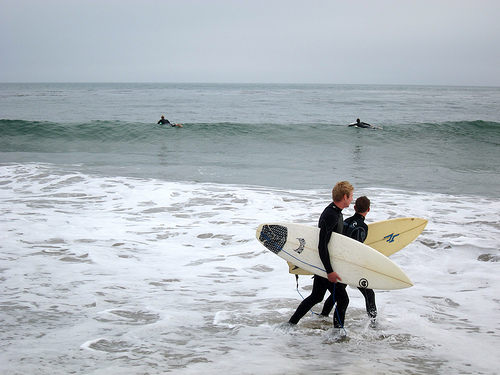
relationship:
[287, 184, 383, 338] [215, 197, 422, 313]
surfer carrying surfboard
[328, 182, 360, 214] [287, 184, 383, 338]
hair on head of surfer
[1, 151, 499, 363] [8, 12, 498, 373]
foam on bed beach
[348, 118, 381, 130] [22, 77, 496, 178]
people floating on top of wave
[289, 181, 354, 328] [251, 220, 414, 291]
man packing surfboard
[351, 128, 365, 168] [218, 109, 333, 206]
reflection on water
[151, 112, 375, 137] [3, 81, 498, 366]
people in ocean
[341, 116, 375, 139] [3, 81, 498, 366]
people in ocean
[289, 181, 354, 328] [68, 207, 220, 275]
man walking in ocean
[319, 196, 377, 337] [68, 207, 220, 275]
man walking in ocean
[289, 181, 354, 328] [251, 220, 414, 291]
man carrying surfboard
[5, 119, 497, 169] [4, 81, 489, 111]
wave in ocean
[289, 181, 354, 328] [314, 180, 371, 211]
man with hair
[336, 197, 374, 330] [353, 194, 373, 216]
man with hair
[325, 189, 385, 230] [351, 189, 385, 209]
man with hair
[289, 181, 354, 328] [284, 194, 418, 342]
man wearing wet suit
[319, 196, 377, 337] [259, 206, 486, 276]
man with surfboards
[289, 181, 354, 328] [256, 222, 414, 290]
man carrying surfboard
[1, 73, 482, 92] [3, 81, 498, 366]
horizon meets ocean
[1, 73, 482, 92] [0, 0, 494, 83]
horizon meets sky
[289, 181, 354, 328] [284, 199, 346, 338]
man wearing wet suit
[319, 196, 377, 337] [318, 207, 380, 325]
man wearing wet suit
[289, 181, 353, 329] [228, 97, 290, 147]
surfer on waves